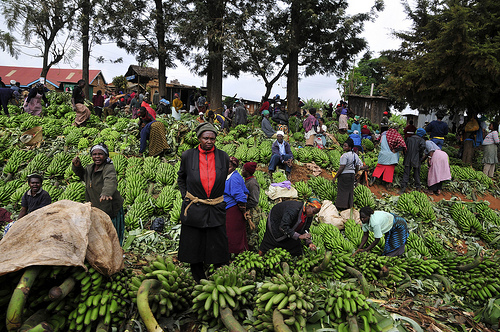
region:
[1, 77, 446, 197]
several people in a field of bananas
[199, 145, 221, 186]
a man wearing a red shirt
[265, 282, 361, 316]
batch of green bananas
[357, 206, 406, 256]
a woman on the ground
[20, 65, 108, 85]
a building with a red roof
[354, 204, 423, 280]
This is a person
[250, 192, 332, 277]
This is a person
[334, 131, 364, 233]
This is a person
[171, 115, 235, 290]
This is a person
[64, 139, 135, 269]
This is a person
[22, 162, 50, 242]
This is a person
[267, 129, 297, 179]
This is a person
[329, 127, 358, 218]
This is a person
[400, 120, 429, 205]
This is a person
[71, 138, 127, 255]
this is a person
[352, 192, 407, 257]
this is a person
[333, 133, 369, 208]
this is a person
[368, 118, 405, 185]
this is a person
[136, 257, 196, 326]
this is a bunch of bananas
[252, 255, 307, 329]
this is a bunch of bananas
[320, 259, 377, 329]
this is a bunch of bananas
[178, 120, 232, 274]
man wearing red shirt and black suit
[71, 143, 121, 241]
woman standing amidst bananas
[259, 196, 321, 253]
woman wearing a head rag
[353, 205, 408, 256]
woman in blue and black dress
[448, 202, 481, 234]
cluster of green bananas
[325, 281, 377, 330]
cluster of green bananas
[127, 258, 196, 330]
cluster of green bananas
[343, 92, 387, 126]
brown wooden building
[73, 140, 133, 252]
This is a woman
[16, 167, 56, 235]
This is a woman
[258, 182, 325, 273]
This is a woman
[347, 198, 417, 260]
A lady picking bananas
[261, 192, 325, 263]
A lady bent over to get a banana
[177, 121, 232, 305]
A woman standing before a pile of bananas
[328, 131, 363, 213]
the back of a woman in front of bananas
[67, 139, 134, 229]
A woman standing in front bananas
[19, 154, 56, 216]
a Smiling man in front of a bunch of bananas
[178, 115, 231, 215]
A woman wearing an orange top and black jacket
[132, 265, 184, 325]
a group of banana still on the truck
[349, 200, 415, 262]
A woman kneeling in a pile of bananas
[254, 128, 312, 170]
A man sitting next to several bananas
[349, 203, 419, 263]
A woman kneeling in a bunch of bananas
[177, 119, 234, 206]
a woman wearing an orange shirt and black jacket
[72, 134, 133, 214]
a lady standing in front of a bunch of bananas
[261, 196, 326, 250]
a Lady bending over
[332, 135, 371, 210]
The back of a woman near bananas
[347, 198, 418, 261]
A woman organizing bananas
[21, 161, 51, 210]
A boy standing in front of bananas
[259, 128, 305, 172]
a man sitting in front of a bunch of bananas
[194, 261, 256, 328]
A bunch of bananas still on the trunk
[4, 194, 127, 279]
a Burlap bag to put bananas in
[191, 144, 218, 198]
The woman is wearing a red shirt.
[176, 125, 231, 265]
The woman is standing next to bananas on the ground.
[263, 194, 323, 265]
A woman is bending over.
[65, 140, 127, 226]
A woman is standing with her arms extended outward.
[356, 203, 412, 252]
A woman is bending over.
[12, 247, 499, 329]
There are bananas on the ground.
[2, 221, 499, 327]
The bananas are green.